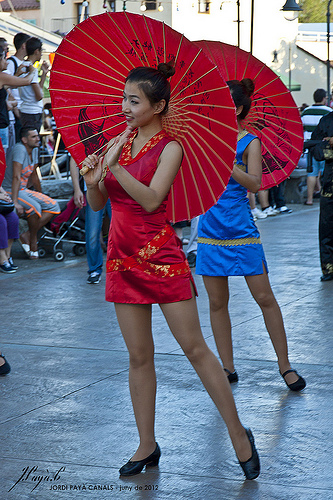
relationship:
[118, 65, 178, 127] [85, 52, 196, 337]
head of woman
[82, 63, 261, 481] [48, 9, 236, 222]
woman holding umbrella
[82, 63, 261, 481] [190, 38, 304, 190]
woman holding umbrella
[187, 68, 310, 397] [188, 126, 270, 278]
woman wears dress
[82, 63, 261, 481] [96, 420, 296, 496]
woman wears shoes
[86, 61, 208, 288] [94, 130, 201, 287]
woman wearing dress